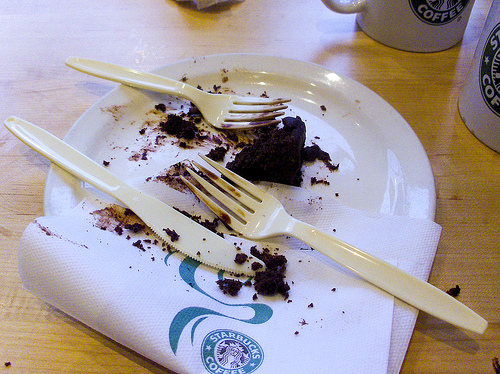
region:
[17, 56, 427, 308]
a white plate with cake crumbs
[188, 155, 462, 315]
a used plastic fork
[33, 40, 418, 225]
two used plastic forks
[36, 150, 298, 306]
a used plastic knife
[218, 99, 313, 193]
a piece of cake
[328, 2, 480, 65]
a coffee mug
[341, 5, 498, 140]
two coffee mugs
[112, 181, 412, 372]
a paper napkin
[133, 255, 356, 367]
a paper napkin with a store logo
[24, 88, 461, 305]
a white plate with plastic eating untensils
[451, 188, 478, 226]
part of a table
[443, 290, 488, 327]
part of a handle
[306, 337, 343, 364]
part of a tissue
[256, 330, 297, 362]
part of a tissue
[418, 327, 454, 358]
part of a table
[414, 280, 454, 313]
part of a handle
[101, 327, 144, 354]
part of a shade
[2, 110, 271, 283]
a white plastic fork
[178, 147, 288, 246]
the tines of a fork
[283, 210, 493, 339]
the handle of a fork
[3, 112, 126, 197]
the handle of a knife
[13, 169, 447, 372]
a white and green napkin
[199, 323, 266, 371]
a round green logo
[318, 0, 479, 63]
a white coffee mug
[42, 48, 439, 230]
a white plate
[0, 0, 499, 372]
a brown wooden table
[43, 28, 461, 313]
A small piece of a already eaten cake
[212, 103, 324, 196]
Piece of the cake is chocolate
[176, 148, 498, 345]
A fork is on the plate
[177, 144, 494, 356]
The fork is made out of plastic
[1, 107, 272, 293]
A plastic knife is on the plate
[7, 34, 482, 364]
Plate is on a wooden table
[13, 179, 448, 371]
A napkin is on the plate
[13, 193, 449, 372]
Napkin is from starbucks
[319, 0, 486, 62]
A white coffee mug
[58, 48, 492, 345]
Two plastic forks are on the plate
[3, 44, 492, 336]
3 dirty utensils shown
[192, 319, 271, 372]
restaurant is Starbucks coffee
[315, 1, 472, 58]
glass coffee mug on table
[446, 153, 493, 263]
light brown wooden table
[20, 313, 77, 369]
table is made of wood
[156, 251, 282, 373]
blue and white design on napkin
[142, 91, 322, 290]
food is almost all gone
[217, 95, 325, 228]
food appears to be chocolate flavored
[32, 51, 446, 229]
the plate is white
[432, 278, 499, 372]
scraps of food on table